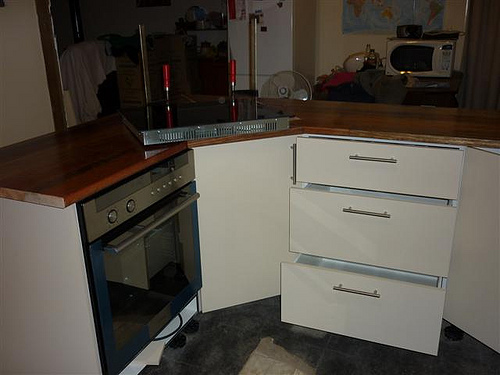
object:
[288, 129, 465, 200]
drawer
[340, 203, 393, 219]
handle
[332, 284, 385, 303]
handle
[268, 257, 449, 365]
drawer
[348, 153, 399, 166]
handle `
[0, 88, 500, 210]
counter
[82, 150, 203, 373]
oven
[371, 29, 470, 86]
microwave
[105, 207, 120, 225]
button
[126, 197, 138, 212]
button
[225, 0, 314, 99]
refrdgerator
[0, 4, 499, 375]
kitchen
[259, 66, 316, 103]
fan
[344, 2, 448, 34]
map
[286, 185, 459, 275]
drawer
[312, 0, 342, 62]
wall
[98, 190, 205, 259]
handle `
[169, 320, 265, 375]
tile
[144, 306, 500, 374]
floor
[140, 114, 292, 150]
grate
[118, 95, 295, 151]
stove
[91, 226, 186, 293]
door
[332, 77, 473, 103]
table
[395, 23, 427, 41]
pot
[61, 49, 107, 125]
sheet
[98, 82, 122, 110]
furniture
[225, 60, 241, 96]
handle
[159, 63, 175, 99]
handle